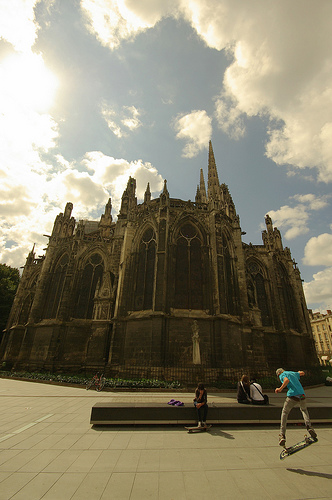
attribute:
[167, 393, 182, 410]
sweater — purple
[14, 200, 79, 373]
tower — damaged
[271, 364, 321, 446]
skateboarder — jumping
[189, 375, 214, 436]
person — taking a break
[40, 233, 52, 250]
gargoyle — protruding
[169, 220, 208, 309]
church windows — stained, glass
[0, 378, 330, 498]
sidewalk — flat, stone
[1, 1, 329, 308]
sky — partly cloudy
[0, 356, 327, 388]
gate — black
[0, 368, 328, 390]
gate — metal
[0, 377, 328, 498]
pavement — gray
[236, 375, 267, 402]
friends — close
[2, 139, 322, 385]
structure — gothic-style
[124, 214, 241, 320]
glass windows — Dramatic, stained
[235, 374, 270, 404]
couple — sitting close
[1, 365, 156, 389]
path — plants